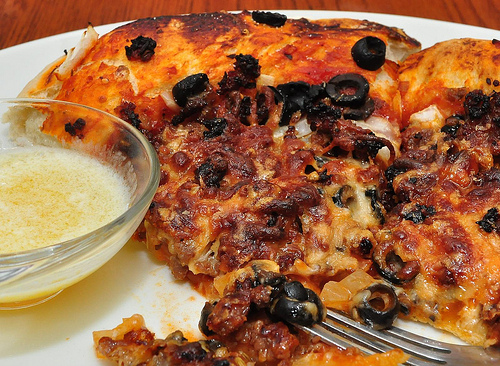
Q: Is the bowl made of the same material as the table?
A: No, the bowl is made of glass and the table is made of wood.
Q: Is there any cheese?
A: Yes, there is cheese.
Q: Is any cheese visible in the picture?
A: Yes, there is cheese.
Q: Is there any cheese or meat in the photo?
A: Yes, there is cheese.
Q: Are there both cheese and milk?
A: No, there is cheese but no milk.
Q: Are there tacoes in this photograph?
A: No, there are no tacoes.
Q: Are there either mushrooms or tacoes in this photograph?
A: No, there are no tacoes or mushrooms.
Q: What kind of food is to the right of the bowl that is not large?
A: The food is cheese.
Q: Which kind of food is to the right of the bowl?
A: The food is cheese.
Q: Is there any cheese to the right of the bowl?
A: Yes, there is cheese to the right of the bowl.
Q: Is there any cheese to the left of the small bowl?
A: No, the cheese is to the right of the bowl.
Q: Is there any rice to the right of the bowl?
A: No, there is cheese to the right of the bowl.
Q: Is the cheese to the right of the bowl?
A: Yes, the cheese is to the right of the bowl.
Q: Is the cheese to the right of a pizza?
A: No, the cheese is to the right of the bowl.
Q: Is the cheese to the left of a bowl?
A: No, the cheese is to the right of a bowl.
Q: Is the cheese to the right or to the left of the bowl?
A: The cheese is to the right of the bowl.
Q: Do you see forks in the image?
A: Yes, there is a fork.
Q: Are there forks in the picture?
A: Yes, there is a fork.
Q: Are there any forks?
A: Yes, there is a fork.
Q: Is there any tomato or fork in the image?
A: Yes, there is a fork.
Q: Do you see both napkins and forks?
A: No, there is a fork but no napkins.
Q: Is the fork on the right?
A: Yes, the fork is on the right of the image.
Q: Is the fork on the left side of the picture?
A: No, the fork is on the right of the image.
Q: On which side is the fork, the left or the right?
A: The fork is on the right of the image.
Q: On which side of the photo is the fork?
A: The fork is on the right of the image.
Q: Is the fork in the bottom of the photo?
A: Yes, the fork is in the bottom of the image.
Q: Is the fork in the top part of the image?
A: No, the fork is in the bottom of the image.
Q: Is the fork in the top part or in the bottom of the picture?
A: The fork is in the bottom of the image.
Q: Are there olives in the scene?
A: Yes, there are olives.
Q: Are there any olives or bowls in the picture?
A: Yes, there are olives.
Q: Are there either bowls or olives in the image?
A: Yes, there are olives.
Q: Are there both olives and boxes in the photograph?
A: No, there are olives but no boxes.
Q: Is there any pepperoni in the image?
A: No, there is no pepperoni.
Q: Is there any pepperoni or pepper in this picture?
A: No, there are no pepperoni or peppers.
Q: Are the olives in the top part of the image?
A: No, the olives are in the bottom of the image.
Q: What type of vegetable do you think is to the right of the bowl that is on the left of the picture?
A: The vegetables are olives.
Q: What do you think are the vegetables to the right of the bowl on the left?
A: The vegetables are olives.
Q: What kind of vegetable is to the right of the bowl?
A: The vegetables are olives.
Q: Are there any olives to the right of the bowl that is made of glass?
A: Yes, there are olives to the right of the bowl.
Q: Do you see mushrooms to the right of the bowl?
A: No, there are olives to the right of the bowl.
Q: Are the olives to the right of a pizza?
A: No, the olives are to the right of a bowl.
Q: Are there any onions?
A: Yes, there are onions.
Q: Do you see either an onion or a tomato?
A: Yes, there are onions.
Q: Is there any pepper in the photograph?
A: No, there are no peppers.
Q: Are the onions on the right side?
A: Yes, the onions are on the right of the image.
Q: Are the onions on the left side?
A: No, the onions are on the right of the image.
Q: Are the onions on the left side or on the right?
A: The onions are on the right of the image.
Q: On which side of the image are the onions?
A: The onions are on the right of the image.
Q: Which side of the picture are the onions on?
A: The onions are on the right of the image.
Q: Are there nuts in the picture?
A: No, there are no nuts.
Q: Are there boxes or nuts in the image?
A: No, there are no nuts or boxes.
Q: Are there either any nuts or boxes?
A: No, there are no nuts or boxes.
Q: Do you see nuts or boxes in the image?
A: No, there are no nuts or boxes.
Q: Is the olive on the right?
A: Yes, the olive is on the right of the image.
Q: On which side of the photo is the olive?
A: The olive is on the right of the image.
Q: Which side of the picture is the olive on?
A: The olive is on the right of the image.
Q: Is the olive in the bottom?
A: No, the olive is in the top of the image.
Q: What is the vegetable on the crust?
A: The vegetable is an olive.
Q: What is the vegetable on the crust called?
A: The vegetable is an olive.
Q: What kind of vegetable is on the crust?
A: The vegetable is an olive.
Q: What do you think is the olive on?
A: The olive is on the crust.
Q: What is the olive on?
A: The olive is on the crust.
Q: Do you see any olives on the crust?
A: Yes, there is an olive on the crust.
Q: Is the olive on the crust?
A: Yes, the olive is on the crust.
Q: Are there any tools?
A: No, there are no tools.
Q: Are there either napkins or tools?
A: No, there are no tools or napkins.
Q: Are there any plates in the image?
A: Yes, there is a plate.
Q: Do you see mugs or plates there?
A: Yes, there is a plate.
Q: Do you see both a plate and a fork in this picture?
A: Yes, there are both a plate and a fork.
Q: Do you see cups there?
A: No, there are no cups.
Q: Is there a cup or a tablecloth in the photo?
A: No, there are no cups or tablecloths.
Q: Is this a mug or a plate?
A: This is a plate.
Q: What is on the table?
A: The plate is on the table.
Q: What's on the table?
A: The plate is on the table.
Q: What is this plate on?
A: The plate is on the table.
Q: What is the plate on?
A: The plate is on the table.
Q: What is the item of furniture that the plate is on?
A: The piece of furniture is a table.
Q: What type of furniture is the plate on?
A: The plate is on the table.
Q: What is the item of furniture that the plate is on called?
A: The piece of furniture is a table.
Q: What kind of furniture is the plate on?
A: The plate is on the table.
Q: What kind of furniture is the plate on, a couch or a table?
A: The plate is on a table.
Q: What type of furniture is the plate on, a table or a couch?
A: The plate is on a table.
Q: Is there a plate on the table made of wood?
A: Yes, there is a plate on the table.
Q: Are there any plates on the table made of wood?
A: Yes, there is a plate on the table.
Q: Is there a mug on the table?
A: No, there is a plate on the table.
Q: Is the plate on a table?
A: Yes, the plate is on a table.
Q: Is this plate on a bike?
A: No, the plate is on a table.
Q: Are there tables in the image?
A: Yes, there is a table.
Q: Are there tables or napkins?
A: Yes, there is a table.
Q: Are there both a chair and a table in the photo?
A: No, there is a table but no chairs.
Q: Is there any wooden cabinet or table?
A: Yes, there is a wood table.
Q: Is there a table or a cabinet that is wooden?
A: Yes, the table is wooden.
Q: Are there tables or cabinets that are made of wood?
A: Yes, the table is made of wood.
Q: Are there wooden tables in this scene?
A: Yes, there is a wood table.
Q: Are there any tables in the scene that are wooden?
A: Yes, there is a table that is wooden.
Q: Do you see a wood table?
A: Yes, there is a table that is made of wood.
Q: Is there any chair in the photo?
A: No, there are no chairs.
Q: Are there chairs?
A: No, there are no chairs.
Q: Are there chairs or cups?
A: No, there are no chairs or cups.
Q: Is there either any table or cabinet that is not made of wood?
A: No, there is a table but it is made of wood.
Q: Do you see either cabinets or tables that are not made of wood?
A: No, there is a table but it is made of wood.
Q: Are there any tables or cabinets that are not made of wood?
A: No, there is a table but it is made of wood.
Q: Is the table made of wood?
A: Yes, the table is made of wood.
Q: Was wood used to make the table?
A: Yes, the table is made of wood.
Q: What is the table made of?
A: The table is made of wood.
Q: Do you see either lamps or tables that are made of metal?
A: No, there is a table but it is made of wood.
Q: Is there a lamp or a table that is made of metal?
A: No, there is a table but it is made of wood.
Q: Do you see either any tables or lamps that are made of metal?
A: No, there is a table but it is made of wood.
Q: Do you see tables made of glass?
A: No, there is a table but it is made of wood.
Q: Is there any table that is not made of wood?
A: No, there is a table but it is made of wood.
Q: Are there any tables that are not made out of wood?
A: No, there is a table but it is made of wood.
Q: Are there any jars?
A: No, there are no jars.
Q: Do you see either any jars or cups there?
A: No, there are no jars or cups.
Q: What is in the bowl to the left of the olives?
A: The butter is in the bowl.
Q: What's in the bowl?
A: The butter is in the bowl.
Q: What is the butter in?
A: The butter is in the bowl.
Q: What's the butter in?
A: The butter is in the bowl.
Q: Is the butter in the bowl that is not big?
A: Yes, the butter is in the bowl.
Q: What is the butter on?
A: The butter is on the crust.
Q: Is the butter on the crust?
A: Yes, the butter is on the crust.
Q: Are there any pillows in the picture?
A: No, there are no pillows.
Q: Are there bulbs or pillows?
A: No, there are no pillows or bulbs.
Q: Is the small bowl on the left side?
A: Yes, the bowl is on the left of the image.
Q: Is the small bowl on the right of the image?
A: No, the bowl is on the left of the image.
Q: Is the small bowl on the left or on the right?
A: The bowl is on the left of the image.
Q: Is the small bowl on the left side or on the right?
A: The bowl is on the left of the image.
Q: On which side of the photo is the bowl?
A: The bowl is on the left of the image.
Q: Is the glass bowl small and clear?
A: Yes, the bowl is small and clear.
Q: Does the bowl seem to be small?
A: Yes, the bowl is small.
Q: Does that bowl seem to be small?
A: Yes, the bowl is small.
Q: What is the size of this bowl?
A: The bowl is small.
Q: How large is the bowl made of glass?
A: The bowl is small.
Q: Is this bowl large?
A: No, the bowl is small.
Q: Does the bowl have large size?
A: No, the bowl is small.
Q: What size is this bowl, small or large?
A: The bowl is small.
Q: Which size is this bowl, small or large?
A: The bowl is small.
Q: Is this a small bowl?
A: Yes, this is a small bowl.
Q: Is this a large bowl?
A: No, this is a small bowl.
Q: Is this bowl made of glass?
A: Yes, the bowl is made of glass.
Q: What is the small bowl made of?
A: The bowl is made of glass.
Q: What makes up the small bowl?
A: The bowl is made of glass.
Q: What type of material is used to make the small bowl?
A: The bowl is made of glass.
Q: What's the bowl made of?
A: The bowl is made of glass.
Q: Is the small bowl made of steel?
A: No, the bowl is made of glass.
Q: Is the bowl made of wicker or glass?
A: The bowl is made of glass.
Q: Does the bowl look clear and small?
A: Yes, the bowl is clear and small.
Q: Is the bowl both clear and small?
A: Yes, the bowl is clear and small.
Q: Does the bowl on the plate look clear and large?
A: No, the bowl is clear but small.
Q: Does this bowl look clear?
A: Yes, the bowl is clear.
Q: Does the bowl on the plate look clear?
A: Yes, the bowl is clear.